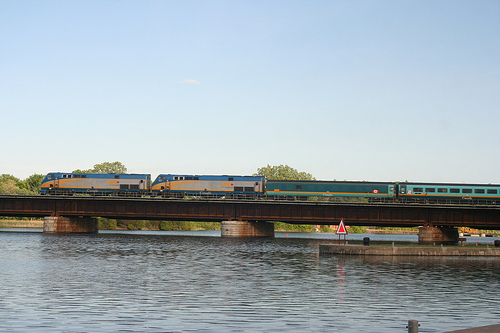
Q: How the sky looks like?
A: Clear.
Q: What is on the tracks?
A: Train.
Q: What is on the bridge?
A: A train.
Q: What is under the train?
A: A river.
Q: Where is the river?
A: Under the bridge.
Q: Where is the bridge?
A: On the river.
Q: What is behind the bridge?
A: Trees.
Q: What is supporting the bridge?
A: Beams in the water.